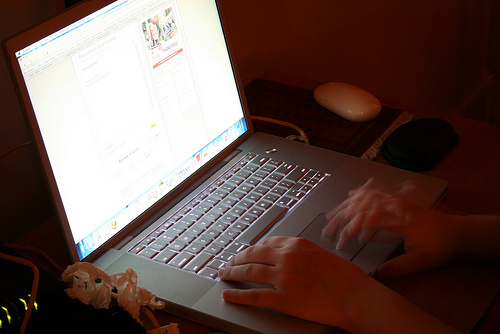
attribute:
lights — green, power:
[1, 290, 45, 331]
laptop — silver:
[7, 1, 449, 331]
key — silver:
[254, 176, 263, 186]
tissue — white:
[48, 246, 137, 315]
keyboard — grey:
[168, 213, 242, 265]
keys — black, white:
[149, 246, 177, 262]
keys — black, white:
[166, 249, 194, 267]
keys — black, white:
[264, 158, 281, 165]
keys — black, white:
[281, 162, 310, 184]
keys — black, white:
[273, 193, 290, 208]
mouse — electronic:
[295, 209, 375, 264]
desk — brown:
[468, 151, 485, 176]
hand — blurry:
[321, 183, 458, 289]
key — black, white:
[166, 249, 195, 268]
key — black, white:
[211, 233, 236, 246]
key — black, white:
[167, 240, 190, 250]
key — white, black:
[136, 245, 162, 258]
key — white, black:
[155, 246, 179, 263]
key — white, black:
[168, 251, 197, 270]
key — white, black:
[184, 242, 204, 254]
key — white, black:
[138, 242, 158, 256]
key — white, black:
[185, 249, 217, 273]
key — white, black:
[202, 241, 225, 254]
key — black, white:
[135, 244, 159, 260]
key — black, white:
[153, 246, 177, 263]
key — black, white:
[182, 247, 213, 272]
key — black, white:
[259, 177, 279, 192]